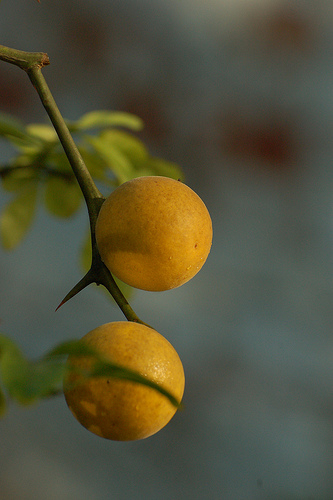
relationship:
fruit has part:
[61, 320, 186, 443] [63, 375, 178, 444]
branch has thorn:
[1, 45, 160, 333] [56, 272, 96, 313]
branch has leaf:
[1, 45, 160, 333] [68, 110, 144, 131]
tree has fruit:
[1, 44, 188, 415] [94, 176, 214, 293]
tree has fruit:
[1, 44, 188, 415] [61, 320, 186, 443]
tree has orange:
[1, 44, 188, 415] [61, 320, 186, 443]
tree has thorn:
[1, 44, 188, 415] [56, 272, 96, 313]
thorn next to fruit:
[56, 272, 96, 313] [94, 176, 214, 293]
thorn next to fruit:
[56, 272, 96, 313] [61, 320, 186, 443]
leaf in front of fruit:
[85, 355, 185, 413] [61, 320, 186, 443]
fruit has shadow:
[94, 176, 214, 293] [94, 230, 143, 260]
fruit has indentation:
[94, 176, 214, 293] [192, 242, 197, 247]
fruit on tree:
[94, 176, 214, 293] [1, 44, 188, 415]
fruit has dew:
[94, 176, 214, 293] [129, 173, 171, 180]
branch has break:
[1, 45, 160, 333] [40, 53, 50, 67]